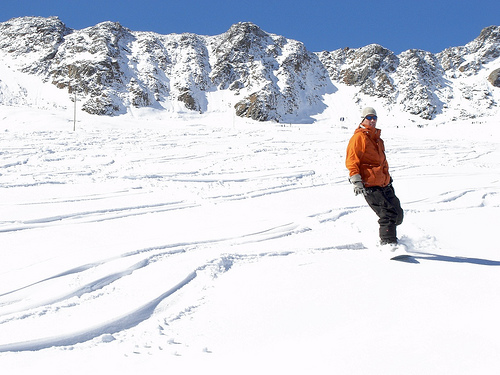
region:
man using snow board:
[344, 102, 411, 269]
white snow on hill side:
[12, 156, 97, 197]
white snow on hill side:
[90, 256, 177, 327]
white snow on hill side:
[240, 278, 301, 333]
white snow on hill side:
[340, 292, 395, 350]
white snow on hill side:
[408, 309, 492, 367]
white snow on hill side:
[72, 258, 167, 336]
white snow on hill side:
[145, 166, 213, 246]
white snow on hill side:
[251, 166, 306, 236]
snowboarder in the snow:
[329, 86, 429, 264]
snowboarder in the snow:
[321, 103, 430, 290]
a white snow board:
[386, 239, 413, 261]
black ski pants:
[359, 183, 403, 240]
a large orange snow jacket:
[343, 128, 390, 185]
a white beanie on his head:
[358, 107, 376, 124]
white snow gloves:
[352, 178, 367, 196]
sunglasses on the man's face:
[366, 115, 377, 121]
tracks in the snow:
[8, 246, 215, 357]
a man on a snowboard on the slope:
[340, 103, 412, 266]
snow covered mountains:
[0, 15, 497, 118]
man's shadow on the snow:
[414, 249, 499, 266]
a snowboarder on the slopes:
[343, 105, 413, 265]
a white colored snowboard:
[375, 240, 416, 265]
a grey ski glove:
[349, 174, 368, 198]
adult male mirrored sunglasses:
[361, 113, 379, 122]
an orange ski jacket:
[345, 123, 392, 187]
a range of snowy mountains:
[3, 13, 497, 123]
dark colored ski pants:
[359, 175, 404, 245]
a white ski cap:
[360, 108, 377, 120]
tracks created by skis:
[3, 178, 498, 353]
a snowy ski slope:
[0, 108, 497, 365]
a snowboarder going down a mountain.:
[338, 103, 421, 269]